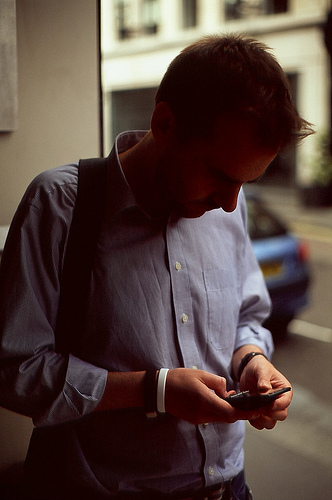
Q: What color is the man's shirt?
A: Blue.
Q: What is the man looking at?
A: Cellphone.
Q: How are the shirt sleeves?
A: Rolled up.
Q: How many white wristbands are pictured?
A: 1.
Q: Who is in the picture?
A: A man.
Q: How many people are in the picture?
A: 1.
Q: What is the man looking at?
A: A phone.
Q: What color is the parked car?
A: Blue.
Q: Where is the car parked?
A: On street.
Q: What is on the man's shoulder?
A: A bag.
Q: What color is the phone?
A: Black.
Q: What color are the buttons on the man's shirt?
A: White.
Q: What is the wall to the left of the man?
A: A window.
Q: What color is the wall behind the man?
A: Beige.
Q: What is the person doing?
A: Looking at his cell phone.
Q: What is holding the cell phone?
A: Hands.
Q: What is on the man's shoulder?
A: A dark strap.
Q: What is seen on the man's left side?
A: A rear end of a vehicle.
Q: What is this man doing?
A: Texting on his phone.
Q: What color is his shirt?
A: Blue.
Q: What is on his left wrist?
A: A watch.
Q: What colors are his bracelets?
A: White and black.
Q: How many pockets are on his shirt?
A: One.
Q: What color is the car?
A: Blue.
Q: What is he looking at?
A: His phone.